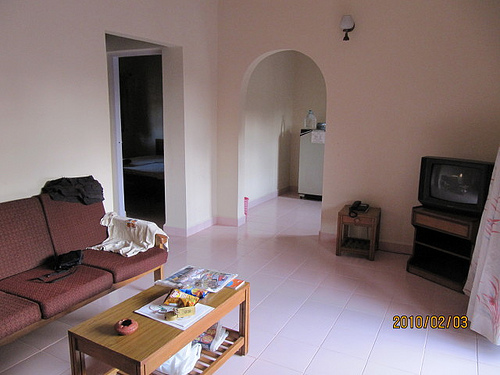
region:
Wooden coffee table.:
[59, 258, 248, 373]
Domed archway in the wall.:
[230, 43, 334, 240]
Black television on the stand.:
[415, 151, 490, 218]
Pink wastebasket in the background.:
[241, 191, 251, 218]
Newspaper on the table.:
[160, 260, 237, 293]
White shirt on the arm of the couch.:
[85, 200, 171, 262]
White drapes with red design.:
[459, 133, 499, 348]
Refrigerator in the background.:
[295, 121, 328, 202]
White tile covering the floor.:
[2, 173, 494, 374]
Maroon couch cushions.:
[0, 175, 163, 340]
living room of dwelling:
[1, 12, 497, 374]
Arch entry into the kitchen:
[230, 44, 328, 248]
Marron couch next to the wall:
[1, 192, 166, 345]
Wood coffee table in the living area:
[66, 265, 252, 374]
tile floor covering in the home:
[5, 187, 494, 374]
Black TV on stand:
[414, 151, 499, 222]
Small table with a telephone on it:
[332, 198, 386, 265]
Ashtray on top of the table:
[109, 313, 143, 339]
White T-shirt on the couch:
[82, 208, 172, 259]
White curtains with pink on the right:
[457, 141, 499, 351]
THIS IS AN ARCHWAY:
[223, 30, 338, 253]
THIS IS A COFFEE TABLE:
[63, 260, 268, 373]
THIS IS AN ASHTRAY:
[112, 313, 139, 333]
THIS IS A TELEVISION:
[393, 146, 498, 219]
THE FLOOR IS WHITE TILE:
[13, 208, 498, 373]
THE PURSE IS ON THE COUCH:
[35, 237, 86, 287]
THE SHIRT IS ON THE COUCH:
[85, 210, 176, 260]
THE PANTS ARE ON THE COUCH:
[43, 158, 103, 213]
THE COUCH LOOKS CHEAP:
[0, 165, 183, 365]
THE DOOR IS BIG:
[96, 13, 203, 248]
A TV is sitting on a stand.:
[416, 150, 496, 223]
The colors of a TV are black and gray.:
[418, 153, 495, 218]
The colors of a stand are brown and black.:
[403, 201, 480, 294]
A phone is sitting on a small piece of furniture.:
[343, 198, 372, 228]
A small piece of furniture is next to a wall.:
[333, 204, 382, 261]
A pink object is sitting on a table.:
[113, 314, 137, 336]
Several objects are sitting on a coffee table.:
[132, 264, 242, 331]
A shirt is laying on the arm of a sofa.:
[87, 210, 171, 260]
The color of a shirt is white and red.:
[86, 209, 170, 260]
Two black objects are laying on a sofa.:
[26, 172, 104, 287]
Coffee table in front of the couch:
[64, 260, 254, 374]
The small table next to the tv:
[326, 197, 392, 267]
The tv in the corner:
[412, 147, 495, 217]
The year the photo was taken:
[391, 310, 426, 334]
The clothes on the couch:
[23, 172, 170, 289]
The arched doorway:
[232, 40, 332, 241]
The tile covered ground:
[2, 190, 499, 372]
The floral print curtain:
[454, 144, 499, 356]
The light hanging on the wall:
[334, 10, 361, 47]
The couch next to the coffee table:
[0, 171, 171, 347]